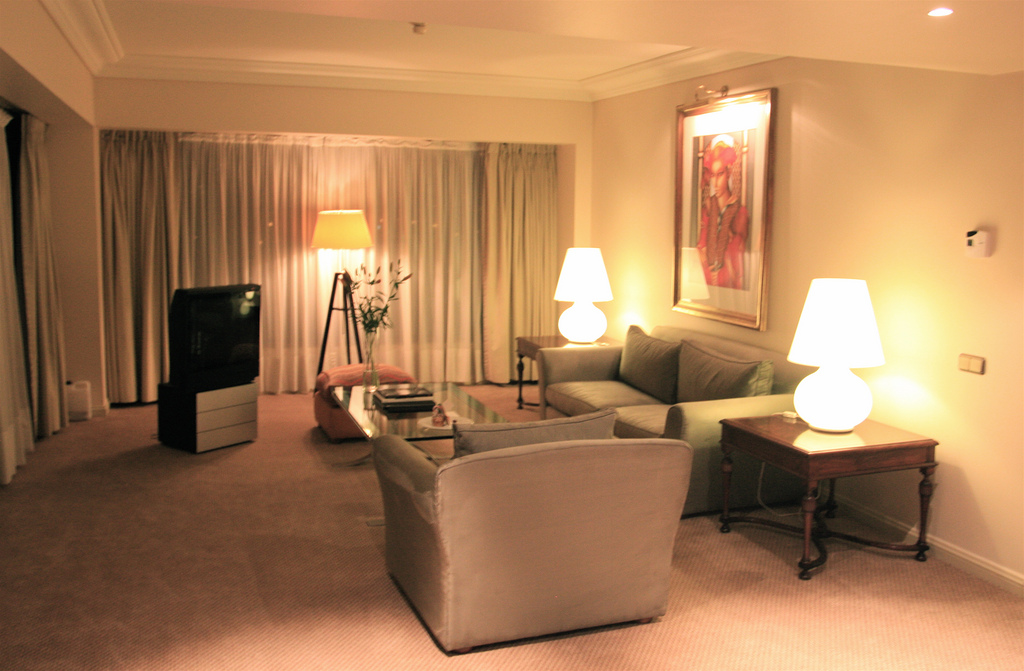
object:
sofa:
[537, 325, 817, 519]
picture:
[676, 87, 780, 331]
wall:
[589, 57, 1024, 590]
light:
[555, 247, 613, 348]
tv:
[167, 284, 262, 391]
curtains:
[99, 128, 554, 402]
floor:
[3, 382, 1024, 670]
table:
[329, 382, 512, 441]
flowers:
[340, 259, 412, 393]